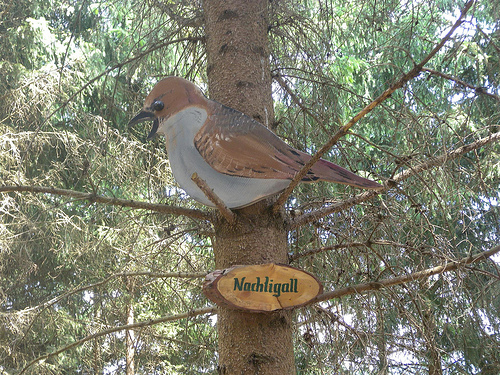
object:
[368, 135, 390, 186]
ground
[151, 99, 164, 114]
eye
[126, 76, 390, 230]
wheel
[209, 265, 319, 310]
name plate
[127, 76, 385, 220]
bird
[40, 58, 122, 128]
branch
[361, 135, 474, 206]
red shirt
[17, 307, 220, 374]
branch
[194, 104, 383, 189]
brown feathers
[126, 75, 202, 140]
bird head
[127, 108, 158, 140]
beak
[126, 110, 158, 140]
open beak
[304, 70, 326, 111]
ground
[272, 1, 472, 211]
branch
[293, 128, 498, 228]
branch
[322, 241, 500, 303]
branch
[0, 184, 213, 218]
branch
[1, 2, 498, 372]
tree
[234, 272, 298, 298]
nachligall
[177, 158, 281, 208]
belly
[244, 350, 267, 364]
sap